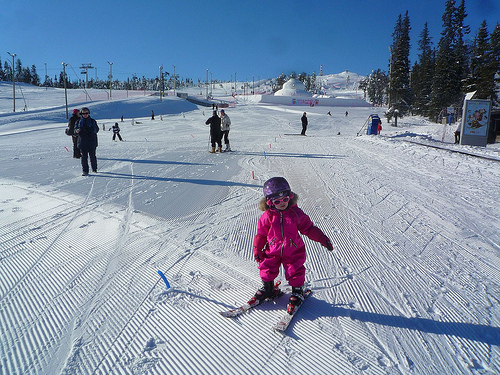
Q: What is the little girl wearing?
A: Pink jacket.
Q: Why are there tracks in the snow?
A: People were skiing there.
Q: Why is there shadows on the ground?
A: It's very sunny.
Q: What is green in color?
A: Trees.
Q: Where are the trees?
A: Next to the people.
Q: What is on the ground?
A: Snow.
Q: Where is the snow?
A: On the ground.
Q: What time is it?
A: Afternoon.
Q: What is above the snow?
A: The sky.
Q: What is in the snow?
A: Tracks.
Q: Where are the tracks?
A: In the snow.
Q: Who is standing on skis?
A: A kid.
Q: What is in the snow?
A: Marks.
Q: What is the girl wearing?
A: Pink snow suit.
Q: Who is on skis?
A: Little girl.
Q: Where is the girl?
A: Ski slope.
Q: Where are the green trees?
A: Slope.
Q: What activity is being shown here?
A: Skiing.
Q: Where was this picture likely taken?
A: A ski resort.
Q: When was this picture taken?
A: Daytime.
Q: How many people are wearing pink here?
A: One.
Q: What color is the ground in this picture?
A: White.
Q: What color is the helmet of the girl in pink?
A: Purple.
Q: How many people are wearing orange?
A: Zero.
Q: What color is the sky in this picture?
A: Blue.